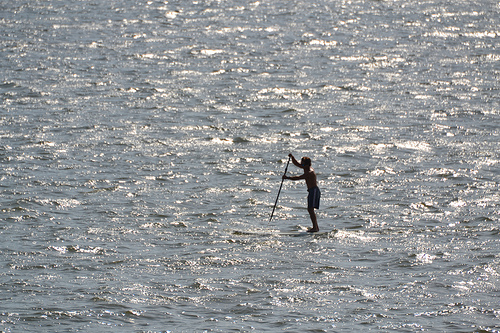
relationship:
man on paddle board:
[281, 152, 323, 233] [277, 224, 365, 239]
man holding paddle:
[281, 152, 323, 233] [271, 154, 290, 218]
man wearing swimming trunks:
[281, 152, 323, 233] [306, 184, 321, 211]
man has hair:
[281, 152, 323, 233] [302, 156, 312, 167]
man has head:
[281, 152, 323, 233] [299, 156, 313, 172]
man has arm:
[281, 152, 323, 233] [286, 152, 302, 170]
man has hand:
[281, 152, 323, 233] [287, 152, 294, 159]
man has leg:
[281, 152, 323, 233] [308, 207, 320, 232]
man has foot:
[281, 152, 323, 233] [306, 227, 321, 234]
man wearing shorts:
[281, 152, 323, 233] [306, 184, 321, 211]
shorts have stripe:
[306, 184, 321, 211] [311, 185, 318, 209]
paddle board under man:
[277, 224, 365, 239] [281, 152, 323, 233]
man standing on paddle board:
[281, 152, 323, 233] [277, 224, 365, 239]